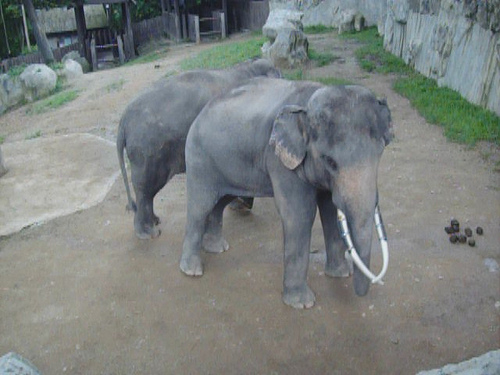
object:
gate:
[87, 28, 127, 67]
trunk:
[332, 150, 378, 297]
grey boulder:
[16, 63, 58, 95]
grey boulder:
[325, 4, 359, 29]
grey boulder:
[58, 57, 83, 82]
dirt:
[272, 138, 296, 169]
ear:
[267, 104, 305, 171]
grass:
[15, 24, 499, 146]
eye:
[325, 157, 337, 170]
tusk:
[369, 204, 388, 285]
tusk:
[335, 202, 386, 284]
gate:
[185, 7, 229, 45]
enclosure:
[1, 2, 498, 373]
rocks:
[253, 0, 500, 119]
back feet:
[134, 222, 161, 240]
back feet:
[202, 232, 231, 253]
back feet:
[181, 244, 206, 276]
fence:
[0, 10, 252, 69]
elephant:
[114, 59, 278, 240]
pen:
[1, 0, 499, 373]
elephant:
[178, 75, 392, 310]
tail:
[114, 123, 137, 216]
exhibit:
[2, 0, 499, 370]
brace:
[334, 210, 356, 251]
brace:
[370, 207, 388, 243]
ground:
[0, 26, 494, 374]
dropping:
[444, 219, 484, 245]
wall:
[2, 1, 499, 115]